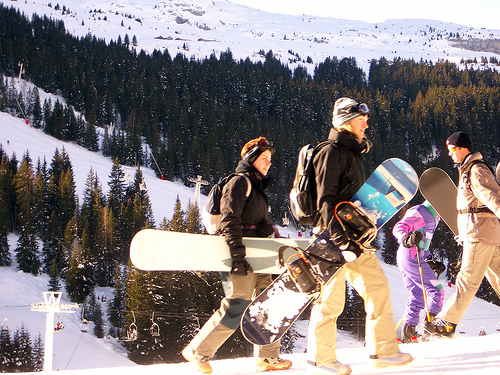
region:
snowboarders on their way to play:
[123, 93, 499, 373]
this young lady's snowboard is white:
[126, 226, 326, 278]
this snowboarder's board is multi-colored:
[238, 155, 420, 348]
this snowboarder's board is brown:
[418, 162, 498, 292]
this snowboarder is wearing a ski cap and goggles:
[327, 95, 372, 140]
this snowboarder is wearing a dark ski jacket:
[213, 135, 279, 258]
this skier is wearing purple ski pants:
[389, 238, 446, 345]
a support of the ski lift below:
[26, 285, 81, 369]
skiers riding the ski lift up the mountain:
[117, 308, 167, 345]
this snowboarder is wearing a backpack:
[283, 140, 323, 227]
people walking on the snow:
[112, 76, 498, 374]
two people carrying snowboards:
[117, 77, 424, 374]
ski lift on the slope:
[26, 283, 76, 373]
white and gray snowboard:
[122, 220, 327, 285]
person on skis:
[376, 168, 461, 343]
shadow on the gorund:
[347, 345, 499, 374]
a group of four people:
[118, 91, 499, 374]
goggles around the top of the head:
[337, 102, 378, 121]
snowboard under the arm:
[114, 216, 334, 288]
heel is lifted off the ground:
[174, 344, 214, 374]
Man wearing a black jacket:
[297, 93, 415, 374]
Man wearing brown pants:
[425, 134, 498, 339]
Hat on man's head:
[327, 93, 366, 127]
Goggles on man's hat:
[337, 101, 370, 126]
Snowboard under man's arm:
[235, 160, 428, 355]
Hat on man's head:
[437, 129, 470, 148]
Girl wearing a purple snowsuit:
[384, 181, 455, 353]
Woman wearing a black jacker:
[183, 124, 290, 374]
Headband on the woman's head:
[239, 131, 272, 165]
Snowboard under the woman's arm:
[122, 218, 318, 286]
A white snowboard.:
[127, 199, 334, 292]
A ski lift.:
[15, 295, 260, 355]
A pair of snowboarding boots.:
[183, 346, 295, 373]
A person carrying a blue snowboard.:
[236, 156, 419, 344]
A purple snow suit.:
[395, 127, 496, 341]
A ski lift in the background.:
[166, 167, 207, 227]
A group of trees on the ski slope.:
[3, 145, 95, 307]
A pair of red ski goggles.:
[242, 130, 282, 175]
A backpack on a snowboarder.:
[286, 143, 321, 227]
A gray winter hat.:
[326, 96, 371, 130]